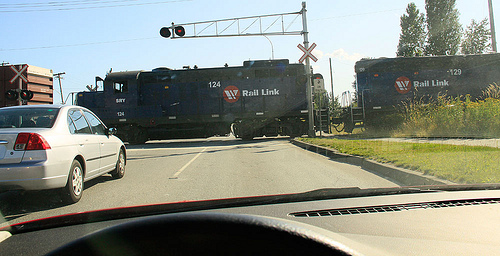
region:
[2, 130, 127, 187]
tail of car at railroad intersection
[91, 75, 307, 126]
train car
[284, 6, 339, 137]
railroad crossing light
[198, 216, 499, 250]
car dashboard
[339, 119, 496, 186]
sidewalk area next to street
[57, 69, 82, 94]
background powerlines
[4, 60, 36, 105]
railroad crossing indicator light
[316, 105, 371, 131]
railroad car connection with stairs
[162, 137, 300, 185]
street area before railroad crossing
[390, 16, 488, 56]
background trees behind railroad crossing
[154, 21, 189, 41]
RED RAILROAD CROSSING SIGNAL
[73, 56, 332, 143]
BLACK RAIL LINK LOCOMOTIVE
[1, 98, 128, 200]
WHITE 4 DOOR CAR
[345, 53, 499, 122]
BLACK RAIL LINK LOCOMOTIVE FACING REVERSE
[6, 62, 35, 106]
RAILROAD CROSSING POLE SIGNAL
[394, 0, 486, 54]
PINE TREES IN THE BACKGROUND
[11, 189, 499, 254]
DASHBOARD FROM THE INTERIOR OF A CAR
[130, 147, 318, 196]
ASPHALT STREET WITH WHITE LINE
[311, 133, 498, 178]
GRASSY AREA ON THE RIGHT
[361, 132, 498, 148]
SIDEWALK ON THE RIGHT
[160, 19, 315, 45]
red lights over a road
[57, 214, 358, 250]
the top of a steering wheel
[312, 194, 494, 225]
a vent on the dash of a car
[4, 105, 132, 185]
a white car waiting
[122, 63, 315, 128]
the left side of a blue train car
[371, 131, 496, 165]
a concrete sidewalk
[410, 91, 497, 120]
tall grass on the side of the road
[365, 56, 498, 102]
a blue train car behind another one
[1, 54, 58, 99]
the back end of a red train car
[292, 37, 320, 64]
the x portion of a train crossing sign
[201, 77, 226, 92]
124 written on the side of a train.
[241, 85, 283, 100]
Rail Link written on the train car.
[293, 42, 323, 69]
Railroad crossing sign on a pole.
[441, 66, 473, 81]
129 written on the train car.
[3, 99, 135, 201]
Silver car waiting for the train to pass.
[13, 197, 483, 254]
Dashboard of a car.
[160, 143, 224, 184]
White line on the road.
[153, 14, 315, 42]
Red stop signal for railroad crossing.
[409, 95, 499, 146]
Tall weeds on the side of the road.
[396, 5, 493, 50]
Tall trees behind the train.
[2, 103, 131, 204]
silver car waiting for train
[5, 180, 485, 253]
interior of car waiting for train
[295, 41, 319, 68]
railroad crossing sign on pole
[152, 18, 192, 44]
railroad lights flashing red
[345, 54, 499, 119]
train car carrying cargo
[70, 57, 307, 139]
train engine with driver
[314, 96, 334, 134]
steps to train entrance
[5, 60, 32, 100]
pole with crossing sign and lights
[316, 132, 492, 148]
sidewalk along the road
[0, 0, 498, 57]
power lines across sky